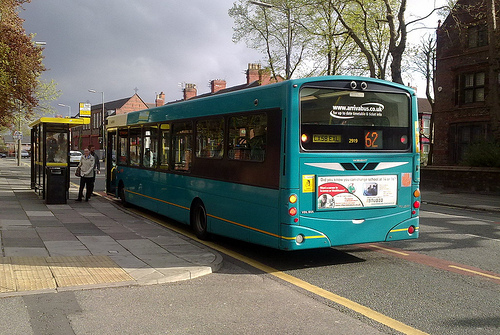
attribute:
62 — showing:
[363, 130, 379, 148]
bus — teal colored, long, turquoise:
[102, 76, 420, 251]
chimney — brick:
[245, 61, 261, 85]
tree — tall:
[378, 2, 450, 87]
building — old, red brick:
[430, 0, 500, 166]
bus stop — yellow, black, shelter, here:
[28, 116, 86, 204]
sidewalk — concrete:
[2, 159, 221, 297]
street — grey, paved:
[16, 156, 498, 334]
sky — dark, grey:
[7, 2, 452, 114]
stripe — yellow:
[72, 181, 422, 334]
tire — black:
[191, 198, 210, 239]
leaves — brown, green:
[1, 1, 47, 135]